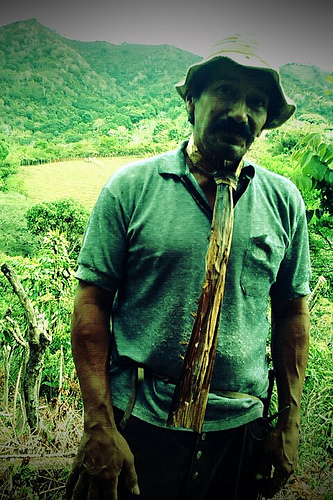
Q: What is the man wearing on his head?
A: Hat.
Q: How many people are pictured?
A: 1.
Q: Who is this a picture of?
A: Man.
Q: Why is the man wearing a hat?
A: Shade.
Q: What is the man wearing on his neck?
A: Tie.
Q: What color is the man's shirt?
A: Green.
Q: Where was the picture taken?
A: Field.